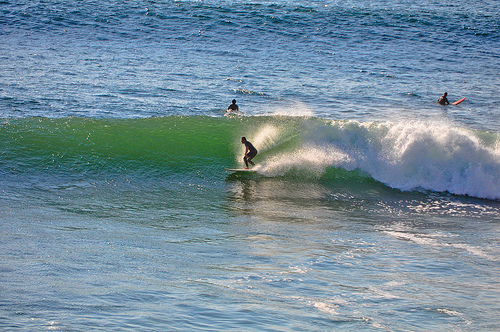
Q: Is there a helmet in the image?
A: No, there are no helmets.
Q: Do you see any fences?
A: No, there are no fences.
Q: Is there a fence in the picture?
A: No, there are no fences.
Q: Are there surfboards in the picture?
A: Yes, there is a surfboard.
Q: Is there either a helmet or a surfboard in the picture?
A: Yes, there is a surfboard.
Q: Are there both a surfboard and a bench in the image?
A: No, there is a surfboard but no benches.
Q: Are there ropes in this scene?
A: No, there are no ropes.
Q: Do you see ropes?
A: No, there are no ropes.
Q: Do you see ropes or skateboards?
A: No, there are no ropes or skateboards.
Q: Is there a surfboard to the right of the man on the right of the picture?
A: Yes, there is a surfboard to the right of the man.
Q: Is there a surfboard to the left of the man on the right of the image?
A: No, the surfboard is to the right of the man.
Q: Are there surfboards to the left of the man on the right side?
A: No, the surfboard is to the right of the man.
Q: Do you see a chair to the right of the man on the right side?
A: No, there is a surfboard to the right of the man.